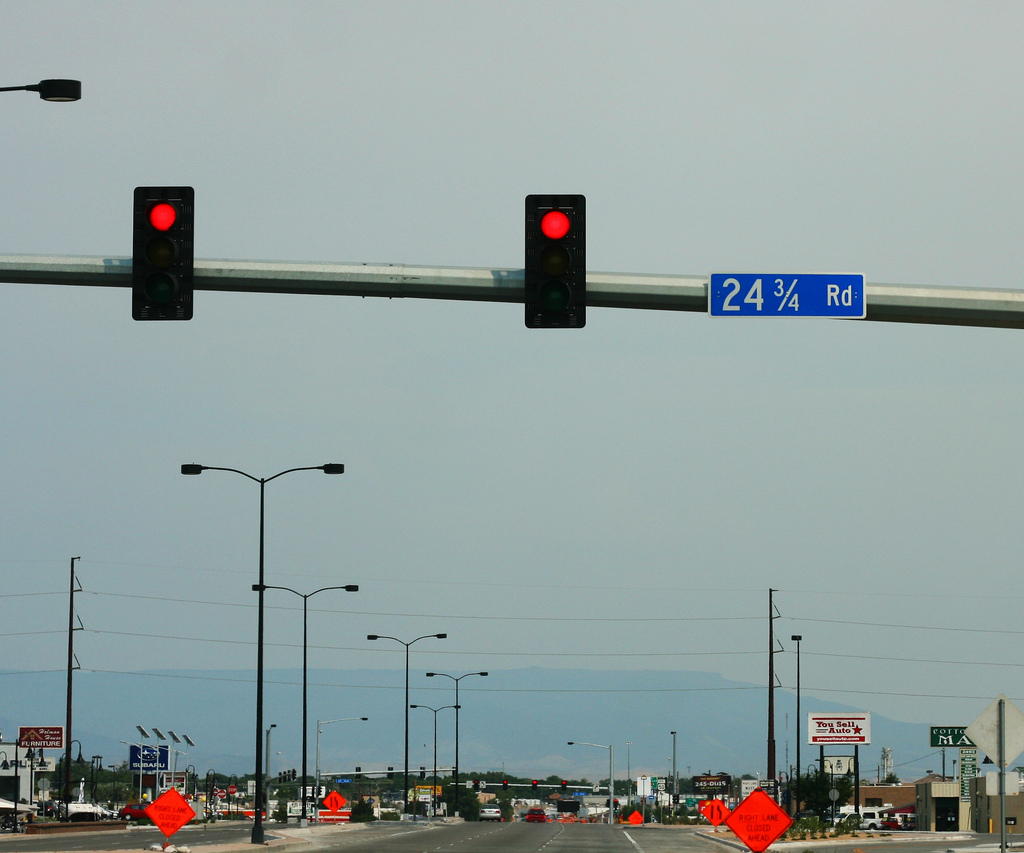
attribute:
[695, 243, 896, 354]
sign — blue, white, street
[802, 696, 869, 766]
sign — white, red, store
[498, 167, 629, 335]
traffic lights — on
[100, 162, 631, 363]
traffic lights — red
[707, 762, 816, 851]
construction signs — on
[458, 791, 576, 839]
cars — at